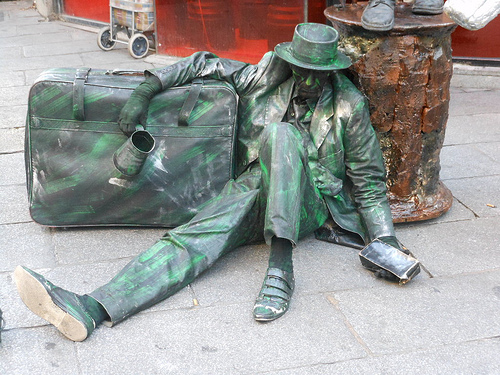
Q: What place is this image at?
A: It is at the sidewalk.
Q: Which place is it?
A: It is a sidewalk.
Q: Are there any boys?
A: No, there are no boys.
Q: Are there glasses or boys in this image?
A: No, there are no boys or glasses.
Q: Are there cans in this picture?
A: Yes, there is a can.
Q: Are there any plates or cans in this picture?
A: Yes, there is a can.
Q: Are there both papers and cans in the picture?
A: No, there is a can but no papers.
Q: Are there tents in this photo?
A: No, there are no tents.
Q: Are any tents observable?
A: No, there are no tents.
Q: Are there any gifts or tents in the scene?
A: No, there are no tents or gifts.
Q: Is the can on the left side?
A: Yes, the can is on the left of the image.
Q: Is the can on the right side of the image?
A: No, the can is on the left of the image.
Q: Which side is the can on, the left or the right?
A: The can is on the left of the image.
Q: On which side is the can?
A: The can is on the left of the image.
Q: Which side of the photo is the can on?
A: The can is on the left of the image.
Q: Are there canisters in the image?
A: No, there are no canisters.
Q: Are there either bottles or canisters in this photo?
A: No, there are no canisters or bottles.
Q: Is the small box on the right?
A: Yes, the box is on the right of the image.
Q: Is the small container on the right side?
A: Yes, the box is on the right of the image.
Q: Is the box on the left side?
A: No, the box is on the right of the image.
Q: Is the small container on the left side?
A: No, the box is on the right of the image.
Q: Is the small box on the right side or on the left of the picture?
A: The box is on the right of the image.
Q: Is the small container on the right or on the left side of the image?
A: The box is on the right of the image.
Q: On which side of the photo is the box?
A: The box is on the right of the image.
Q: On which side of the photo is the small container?
A: The box is on the right of the image.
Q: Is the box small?
A: Yes, the box is small.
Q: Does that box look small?
A: Yes, the box is small.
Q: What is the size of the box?
A: The box is small.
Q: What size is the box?
A: The box is small.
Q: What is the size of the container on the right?
A: The box is small.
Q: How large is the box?
A: The box is small.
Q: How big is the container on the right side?
A: The box is small.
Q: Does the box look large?
A: No, the box is small.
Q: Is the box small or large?
A: The box is small.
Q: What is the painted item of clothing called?
A: The clothing item is a jacket.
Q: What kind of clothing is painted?
A: The clothing is a jacket.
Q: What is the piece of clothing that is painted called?
A: The clothing item is a jacket.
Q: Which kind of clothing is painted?
A: The clothing is a jacket.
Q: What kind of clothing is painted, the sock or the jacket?
A: The jacket is painted.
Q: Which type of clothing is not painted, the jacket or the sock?
A: The sock is not painted.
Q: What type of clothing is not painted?
A: The clothing is a sock.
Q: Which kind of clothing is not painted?
A: The clothing is a sock.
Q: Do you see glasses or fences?
A: No, there are no fences or glasses.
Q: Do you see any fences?
A: No, there are no fences.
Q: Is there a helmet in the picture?
A: No, there are no helmets.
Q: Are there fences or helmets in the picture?
A: No, there are no helmets or fences.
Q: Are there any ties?
A: Yes, there is a tie.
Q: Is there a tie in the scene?
A: Yes, there is a tie.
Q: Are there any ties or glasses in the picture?
A: Yes, there is a tie.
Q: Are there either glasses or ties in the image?
A: Yes, there is a tie.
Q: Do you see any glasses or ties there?
A: Yes, there is a tie.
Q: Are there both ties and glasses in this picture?
A: No, there is a tie but no glasses.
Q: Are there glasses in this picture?
A: No, there are no glasses.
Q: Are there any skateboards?
A: No, there are no skateboards.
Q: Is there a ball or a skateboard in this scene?
A: No, there are no skateboards or balls.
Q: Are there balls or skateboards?
A: No, there are no skateboards or balls.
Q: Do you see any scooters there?
A: No, there are no scooters.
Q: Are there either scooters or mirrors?
A: No, there are no scooters or mirrors.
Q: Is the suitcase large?
A: Yes, the suitcase is large.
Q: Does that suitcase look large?
A: Yes, the suitcase is large.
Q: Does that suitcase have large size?
A: Yes, the suitcase is large.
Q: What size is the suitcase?
A: The suitcase is large.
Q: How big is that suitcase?
A: The suitcase is large.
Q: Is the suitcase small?
A: No, the suitcase is large.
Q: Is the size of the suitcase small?
A: No, the suitcase is large.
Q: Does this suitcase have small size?
A: No, the suitcase is large.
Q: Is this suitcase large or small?
A: The suitcase is large.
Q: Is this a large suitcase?
A: Yes, this is a large suitcase.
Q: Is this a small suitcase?
A: No, this is a large suitcase.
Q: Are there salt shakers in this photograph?
A: No, there are no salt shakers.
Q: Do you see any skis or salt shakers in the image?
A: No, there are no salt shakers or skis.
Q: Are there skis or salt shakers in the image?
A: No, there are no salt shakers or skis.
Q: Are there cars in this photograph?
A: No, there are no cars.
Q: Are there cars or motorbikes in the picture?
A: No, there are no cars or motorbikes.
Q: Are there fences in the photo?
A: No, there are no fences.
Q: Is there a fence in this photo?
A: No, there are no fences.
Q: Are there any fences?
A: No, there are no fences.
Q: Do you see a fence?
A: No, there are no fences.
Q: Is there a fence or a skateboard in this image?
A: No, there are no fences or skateboards.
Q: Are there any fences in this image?
A: No, there are no fences.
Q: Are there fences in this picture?
A: No, there are no fences.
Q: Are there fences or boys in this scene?
A: No, there are no fences or boys.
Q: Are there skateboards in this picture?
A: No, there are no skateboards.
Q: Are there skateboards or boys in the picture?
A: No, there are no skateboards or boys.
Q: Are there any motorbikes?
A: No, there are no motorbikes.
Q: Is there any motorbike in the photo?
A: No, there are no motorcycles.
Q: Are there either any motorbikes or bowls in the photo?
A: No, there are no motorbikes or bowls.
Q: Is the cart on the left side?
A: Yes, the cart is on the left of the image.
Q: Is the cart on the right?
A: No, the cart is on the left of the image.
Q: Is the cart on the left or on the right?
A: The cart is on the left of the image.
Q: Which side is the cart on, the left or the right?
A: The cart is on the left of the image.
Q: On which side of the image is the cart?
A: The cart is on the left of the image.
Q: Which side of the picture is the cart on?
A: The cart is on the left of the image.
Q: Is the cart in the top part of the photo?
A: Yes, the cart is in the top of the image.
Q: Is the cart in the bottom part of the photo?
A: No, the cart is in the top of the image.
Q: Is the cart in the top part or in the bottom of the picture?
A: The cart is in the top of the image.